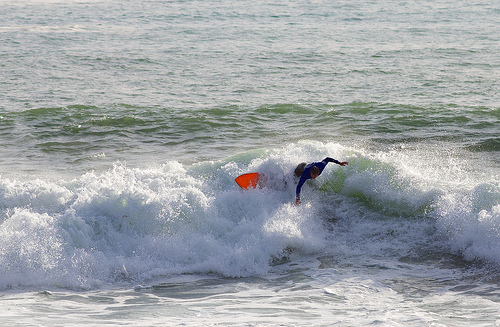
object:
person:
[294, 157, 348, 206]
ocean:
[0, 1, 499, 137]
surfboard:
[235, 172, 261, 191]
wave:
[0, 140, 296, 292]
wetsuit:
[292, 157, 340, 200]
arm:
[296, 177, 308, 201]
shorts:
[294, 162, 307, 178]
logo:
[305, 162, 314, 168]